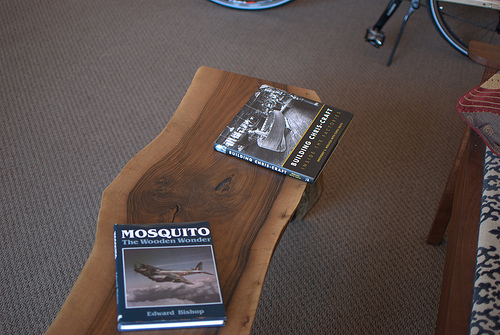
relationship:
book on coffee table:
[214, 81, 354, 183] [44, 64, 324, 335]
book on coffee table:
[113, 221, 228, 330] [44, 64, 324, 335]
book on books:
[214, 81, 354, 183] [107, 81, 353, 330]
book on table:
[113, 221, 228, 330] [106, 66, 236, 216]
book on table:
[214, 81, 354, 183] [106, 66, 236, 216]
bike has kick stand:
[196, 0, 499, 67] [337, 7, 454, 89]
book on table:
[113, 221, 228, 330] [68, 69, 315, 332]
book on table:
[214, 81, 354, 183] [68, 69, 315, 332]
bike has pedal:
[199, 4, 497, 62] [344, 14, 381, 55]